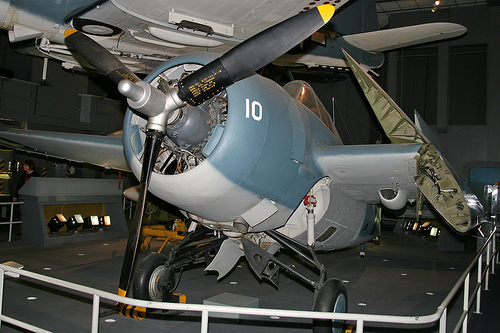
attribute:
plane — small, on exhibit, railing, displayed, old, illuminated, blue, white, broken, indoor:
[62, 5, 488, 332]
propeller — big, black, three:
[63, 4, 336, 299]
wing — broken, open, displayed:
[316, 45, 489, 236]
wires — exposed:
[419, 146, 457, 199]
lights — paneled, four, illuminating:
[47, 207, 112, 234]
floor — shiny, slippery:
[1, 219, 499, 333]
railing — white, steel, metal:
[0, 196, 498, 332]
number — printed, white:
[244, 94, 265, 126]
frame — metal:
[158, 194, 326, 313]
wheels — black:
[130, 251, 349, 332]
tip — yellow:
[317, 1, 336, 23]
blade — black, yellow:
[179, 2, 336, 107]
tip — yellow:
[63, 27, 77, 37]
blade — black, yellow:
[62, 27, 141, 84]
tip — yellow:
[116, 287, 127, 297]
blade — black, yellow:
[116, 127, 166, 298]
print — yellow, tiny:
[187, 68, 223, 98]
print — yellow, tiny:
[114, 67, 140, 85]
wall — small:
[17, 176, 131, 251]